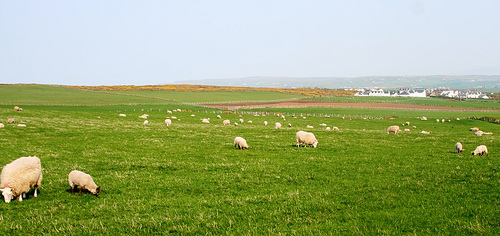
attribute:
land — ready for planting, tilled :
[270, 94, 417, 119]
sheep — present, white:
[1, 152, 47, 205]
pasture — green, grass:
[2, 85, 497, 235]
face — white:
[1, 184, 13, 203]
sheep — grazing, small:
[66, 169, 106, 197]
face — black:
[94, 184, 104, 195]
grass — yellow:
[77, 86, 362, 100]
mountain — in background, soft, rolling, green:
[185, 74, 498, 91]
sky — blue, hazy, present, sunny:
[1, 1, 499, 76]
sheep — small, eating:
[233, 133, 250, 152]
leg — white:
[33, 184, 40, 199]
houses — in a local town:
[435, 88, 492, 102]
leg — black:
[69, 185, 77, 198]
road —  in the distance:
[205, 97, 299, 109]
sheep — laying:
[473, 126, 494, 139]